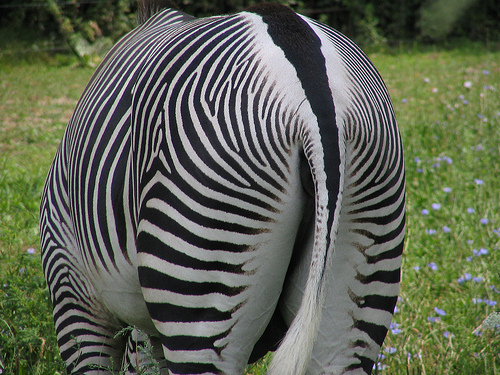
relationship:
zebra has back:
[38, 0, 407, 373] [152, 320, 269, 375]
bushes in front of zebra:
[316, 0, 498, 54] [38, 0, 407, 373]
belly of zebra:
[79, 257, 160, 338] [38, 0, 407, 373]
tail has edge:
[266, 118, 346, 374] [266, 279, 327, 373]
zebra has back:
[38, 0, 407, 373] [180, 53, 250, 313]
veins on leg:
[217, 271, 277, 350] [165, 201, 283, 372]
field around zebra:
[396, 76, 483, 224] [56, 17, 478, 370]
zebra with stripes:
[56, 17, 478, 370] [91, 47, 211, 175]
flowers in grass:
[388, 68, 495, 373] [4, 46, 498, 371]